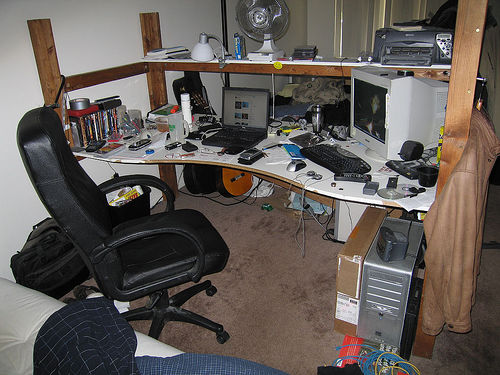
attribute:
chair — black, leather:
[17, 109, 231, 346]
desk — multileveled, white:
[76, 103, 440, 205]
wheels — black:
[201, 281, 231, 346]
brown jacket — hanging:
[421, 108, 499, 341]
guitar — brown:
[175, 77, 253, 198]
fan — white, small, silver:
[235, 5, 289, 59]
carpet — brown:
[134, 197, 493, 370]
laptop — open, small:
[204, 88, 273, 151]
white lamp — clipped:
[190, 32, 231, 70]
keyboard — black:
[300, 139, 369, 178]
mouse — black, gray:
[286, 161, 308, 174]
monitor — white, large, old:
[349, 68, 442, 155]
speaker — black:
[398, 142, 423, 164]